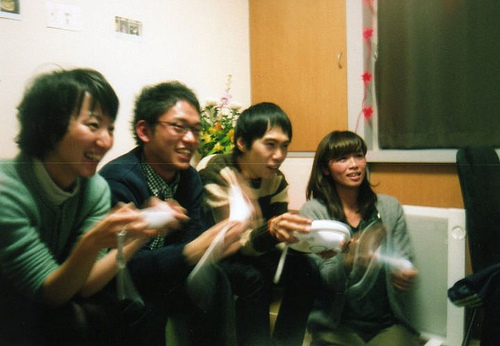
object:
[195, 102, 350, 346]
man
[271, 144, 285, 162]
nose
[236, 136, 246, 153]
ear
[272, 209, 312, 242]
hand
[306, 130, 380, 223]
hair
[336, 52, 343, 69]
door handle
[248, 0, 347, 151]
door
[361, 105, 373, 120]
star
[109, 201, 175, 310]
remote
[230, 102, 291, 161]
hair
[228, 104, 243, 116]
flowers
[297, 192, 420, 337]
sweater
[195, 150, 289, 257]
sweater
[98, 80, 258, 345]
man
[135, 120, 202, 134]
glasses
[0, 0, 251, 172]
wall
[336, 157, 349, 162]
eye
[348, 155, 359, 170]
nose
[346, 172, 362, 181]
mouth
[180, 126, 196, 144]
nose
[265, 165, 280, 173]
mouth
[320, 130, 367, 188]
head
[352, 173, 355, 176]
teeth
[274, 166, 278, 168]
teeth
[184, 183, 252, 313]
wii remote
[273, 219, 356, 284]
wii steering wheel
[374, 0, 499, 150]
curtains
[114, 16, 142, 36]
picture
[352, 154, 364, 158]
eye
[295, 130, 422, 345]
woman